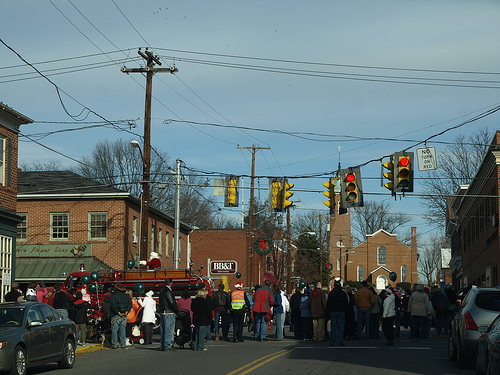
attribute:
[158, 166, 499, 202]
wires — black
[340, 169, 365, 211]
lights — red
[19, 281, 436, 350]
people — congregated, crowd, large, watching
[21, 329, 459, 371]
street — crowded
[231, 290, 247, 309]
vest — yellow, orange, reflective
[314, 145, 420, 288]
church — brick, brown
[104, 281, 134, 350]
man — standing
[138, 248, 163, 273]
santa — waving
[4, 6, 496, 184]
sky — blue, clear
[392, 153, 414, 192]
stoplight — red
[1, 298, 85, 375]
car — parked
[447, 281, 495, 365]
car — parked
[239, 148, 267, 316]
pole — wooden, tall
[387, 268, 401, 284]
balloon — floating, green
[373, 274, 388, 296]
door — white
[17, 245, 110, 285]
awning — green